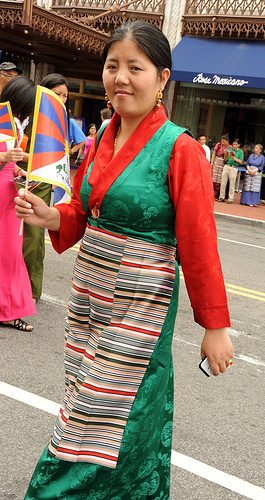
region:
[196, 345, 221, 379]
cell phone in hand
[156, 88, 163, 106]
yellow and red ear rings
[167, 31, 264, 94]
blue awning with white writing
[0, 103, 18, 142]
red and blue flag with yellow boarder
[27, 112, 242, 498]
red and green dress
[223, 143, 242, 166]
green button down shirt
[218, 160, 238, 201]
light colored khaki pants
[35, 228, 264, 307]
yellow painted dividing lines on road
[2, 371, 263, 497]
white line on road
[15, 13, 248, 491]
woman with flag in hand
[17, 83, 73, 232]
flag in woman's hand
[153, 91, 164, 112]
earring in woman's left ear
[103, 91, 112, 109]
earring in woman's right ear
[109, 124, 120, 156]
necklace on the woman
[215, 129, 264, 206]
people standing on the sidewalk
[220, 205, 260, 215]
sidewalk with pedestrians on it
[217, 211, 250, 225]
curb on the sidewalk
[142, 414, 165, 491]
print on the dress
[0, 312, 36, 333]
sandal on another person's foot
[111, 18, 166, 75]
girl has dark hair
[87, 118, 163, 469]
girl has red and green dress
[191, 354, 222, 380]
girl carries white phone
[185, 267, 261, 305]
double yellow line behind woman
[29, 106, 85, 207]
woman is holding flag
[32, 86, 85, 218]
red white yellow and blue flag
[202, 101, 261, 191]
people standing on sidewalk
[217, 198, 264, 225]
sidewalk is orange brick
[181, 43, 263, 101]
blue and white awning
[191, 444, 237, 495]
the line is white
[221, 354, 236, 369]
the woman is wearing a ring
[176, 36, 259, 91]
the awning is blue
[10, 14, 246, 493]
the woman is holding a flag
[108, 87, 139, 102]
the woman has a mouth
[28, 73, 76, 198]
the flag is red and blue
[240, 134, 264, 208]
the dress is purple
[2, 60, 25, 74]
the cap is gray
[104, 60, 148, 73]
the woman has eyes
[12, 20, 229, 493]
woman in colorful dress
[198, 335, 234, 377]
white and black cellphone in left hand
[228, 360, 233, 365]
gold ring with red stone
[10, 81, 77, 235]
flag on wooden stick in right hand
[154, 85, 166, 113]
long yellow, red and blue earring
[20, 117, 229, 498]
beautiful red and green robe with striped front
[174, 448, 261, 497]
white line on road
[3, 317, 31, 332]
foot wearing sandal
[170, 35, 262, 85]
blue awning with white lettering